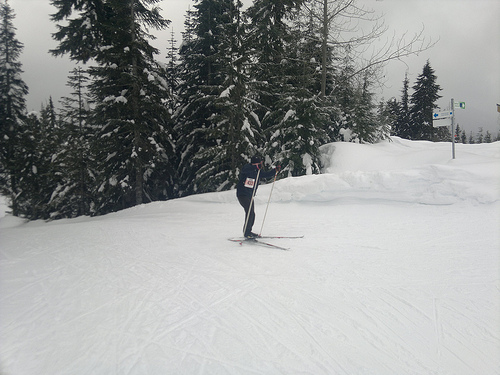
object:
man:
[238, 151, 263, 237]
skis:
[228, 236, 305, 252]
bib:
[245, 176, 258, 189]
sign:
[433, 109, 450, 130]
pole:
[451, 95, 455, 162]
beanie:
[251, 152, 261, 164]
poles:
[237, 170, 268, 235]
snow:
[0, 141, 500, 350]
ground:
[0, 139, 500, 375]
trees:
[0, 15, 494, 222]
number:
[243, 177, 254, 190]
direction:
[431, 110, 454, 129]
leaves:
[76, 81, 249, 190]